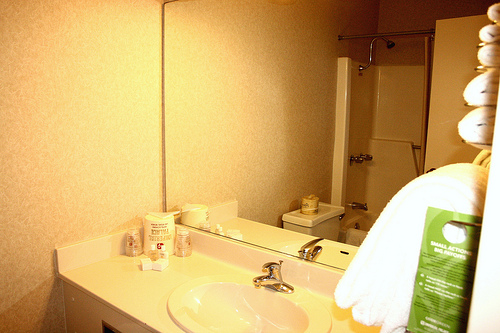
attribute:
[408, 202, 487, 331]
door tag — green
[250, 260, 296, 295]
fixtures — chrome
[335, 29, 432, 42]
pole — metal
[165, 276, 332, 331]
sink — white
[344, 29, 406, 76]
shower head — long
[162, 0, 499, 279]
mirror — large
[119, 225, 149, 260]
cup — upside down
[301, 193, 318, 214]
toilet paper — extra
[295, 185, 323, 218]
tissue — white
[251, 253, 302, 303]
faucet — metal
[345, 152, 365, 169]
shower handle — metal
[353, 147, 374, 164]
shower handle — metal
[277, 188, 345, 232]
toilet — white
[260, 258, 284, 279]
water control — single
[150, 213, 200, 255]
cups — plastic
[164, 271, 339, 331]
sink — white, porcelain 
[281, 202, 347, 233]
toilet — white